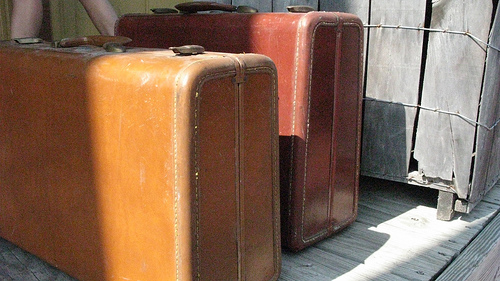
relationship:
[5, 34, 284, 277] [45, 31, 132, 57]
briefcase has handle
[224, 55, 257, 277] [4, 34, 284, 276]
seam in luggage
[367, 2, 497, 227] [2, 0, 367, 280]
box beside suitcases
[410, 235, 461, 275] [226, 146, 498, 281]
nails on stand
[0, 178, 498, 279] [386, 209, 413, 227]
floor has section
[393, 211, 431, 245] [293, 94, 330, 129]
sunlight on ground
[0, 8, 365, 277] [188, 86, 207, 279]
suitcase has stitched seams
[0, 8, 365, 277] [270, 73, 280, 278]
suitcase has stitched seams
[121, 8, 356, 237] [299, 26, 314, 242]
suitcase has stitched seams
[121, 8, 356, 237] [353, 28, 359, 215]
suitcase has stitched seams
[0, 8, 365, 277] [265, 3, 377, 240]
suitcase next suitcase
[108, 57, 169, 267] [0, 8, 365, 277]
sun on suitcase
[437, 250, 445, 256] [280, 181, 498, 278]
screws on decking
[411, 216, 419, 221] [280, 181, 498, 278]
screws on decking